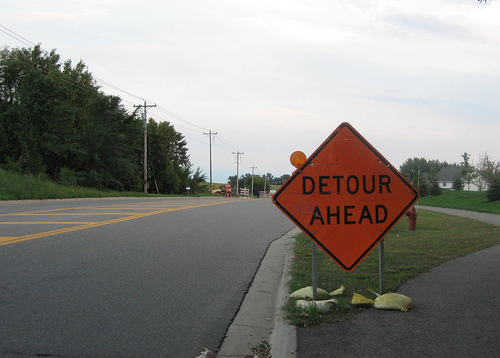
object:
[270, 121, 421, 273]
detour sign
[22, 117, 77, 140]
leaves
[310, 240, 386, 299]
posts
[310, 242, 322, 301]
post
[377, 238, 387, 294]
post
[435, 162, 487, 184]
roof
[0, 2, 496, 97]
sky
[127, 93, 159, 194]
telephone pole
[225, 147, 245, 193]
telephone pole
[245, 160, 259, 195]
telephone pole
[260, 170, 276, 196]
telephone pole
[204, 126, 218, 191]
telephone pole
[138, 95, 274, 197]
row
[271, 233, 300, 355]
curb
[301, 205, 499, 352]
sidewalk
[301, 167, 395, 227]
lettering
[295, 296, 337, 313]
bags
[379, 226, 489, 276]
grass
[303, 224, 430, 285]
grass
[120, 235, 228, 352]
pavement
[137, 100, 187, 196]
pole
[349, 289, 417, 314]
bag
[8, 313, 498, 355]
ground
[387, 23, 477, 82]
clouds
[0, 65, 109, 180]
trees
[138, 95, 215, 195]
poles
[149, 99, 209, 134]
wires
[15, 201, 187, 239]
lines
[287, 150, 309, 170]
light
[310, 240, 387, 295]
poles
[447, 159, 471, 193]
trees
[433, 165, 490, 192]
house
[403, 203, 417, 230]
fire-hydrant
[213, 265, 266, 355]
border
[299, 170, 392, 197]
word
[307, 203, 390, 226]
word